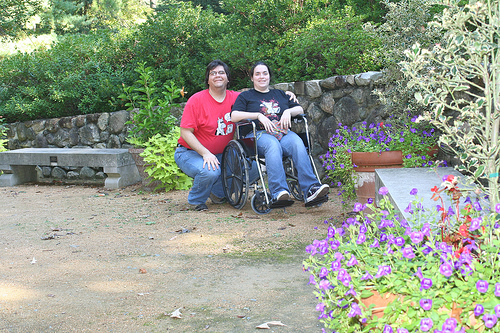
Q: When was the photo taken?
A: Daytime.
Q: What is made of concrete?
A: Benches.